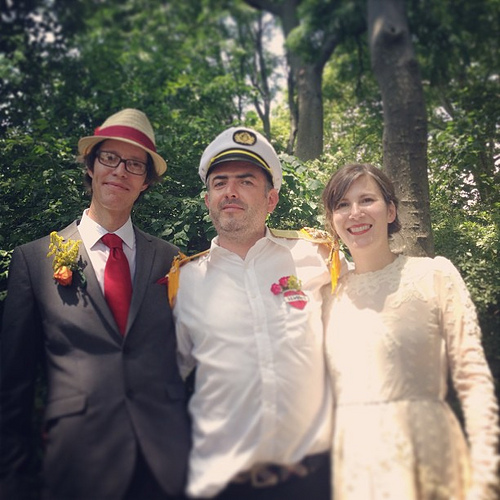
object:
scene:
[0, 0, 500, 500]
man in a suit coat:
[0, 214, 190, 500]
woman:
[318, 156, 500, 500]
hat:
[77, 108, 167, 177]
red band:
[94, 124, 158, 153]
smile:
[101, 179, 130, 195]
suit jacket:
[0, 218, 193, 499]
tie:
[101, 232, 133, 336]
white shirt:
[76, 206, 137, 331]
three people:
[0, 105, 500, 500]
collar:
[80, 209, 135, 250]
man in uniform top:
[168, 125, 346, 500]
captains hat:
[197, 125, 282, 194]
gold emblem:
[233, 129, 258, 146]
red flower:
[52, 266, 73, 288]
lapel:
[56, 219, 121, 342]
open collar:
[210, 236, 269, 265]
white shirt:
[169, 223, 334, 500]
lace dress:
[320, 253, 500, 500]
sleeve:
[435, 254, 500, 500]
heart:
[283, 290, 308, 311]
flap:
[43, 393, 88, 426]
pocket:
[42, 395, 89, 450]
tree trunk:
[370, 1, 430, 250]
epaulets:
[165, 225, 341, 312]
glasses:
[93, 147, 151, 176]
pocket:
[280, 290, 314, 327]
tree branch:
[250, 1, 367, 164]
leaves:
[0, 0, 500, 297]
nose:
[348, 204, 366, 221]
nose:
[111, 161, 128, 179]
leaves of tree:
[0, 0, 328, 286]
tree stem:
[253, 78, 273, 140]